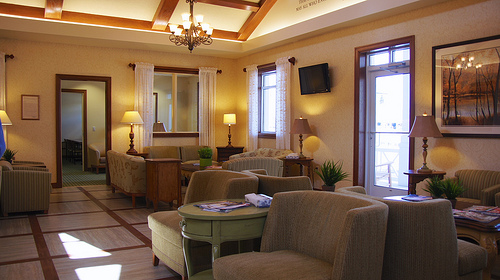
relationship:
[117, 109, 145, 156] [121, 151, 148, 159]
lamp on table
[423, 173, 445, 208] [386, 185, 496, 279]
plant on table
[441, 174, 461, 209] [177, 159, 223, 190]
plant on table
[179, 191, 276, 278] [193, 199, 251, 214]
table with magazine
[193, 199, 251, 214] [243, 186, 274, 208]
magazine and tissues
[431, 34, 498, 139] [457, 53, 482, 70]
painting with light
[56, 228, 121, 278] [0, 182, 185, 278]
sunlight on floor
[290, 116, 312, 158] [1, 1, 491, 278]
lamp in th room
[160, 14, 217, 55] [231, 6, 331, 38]
lights hanging from ceiling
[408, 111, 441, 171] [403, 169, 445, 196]
lamp on end table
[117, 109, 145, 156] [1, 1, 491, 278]
lamp in corner of room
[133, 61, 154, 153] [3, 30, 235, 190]
curatin on wall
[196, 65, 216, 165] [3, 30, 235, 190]
curatin on wall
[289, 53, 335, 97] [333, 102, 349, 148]
television on wall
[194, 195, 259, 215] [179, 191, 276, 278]
magazine on table